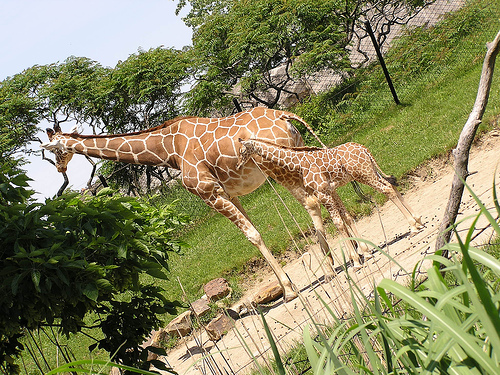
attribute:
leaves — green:
[55, 232, 163, 295]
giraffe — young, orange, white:
[236, 136, 425, 273]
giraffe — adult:
[42, 107, 373, 301]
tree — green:
[2, 127, 200, 370]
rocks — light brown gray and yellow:
[146, 271, 266, 345]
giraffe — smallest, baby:
[238, 139, 420, 259]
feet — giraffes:
[276, 273, 336, 289]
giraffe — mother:
[49, 107, 329, 282]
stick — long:
[435, 33, 496, 263]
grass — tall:
[319, 254, 496, 370]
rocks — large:
[177, 279, 277, 331]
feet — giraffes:
[274, 217, 416, 272]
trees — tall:
[3, 0, 350, 129]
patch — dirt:
[176, 154, 496, 328]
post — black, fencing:
[361, 20, 401, 101]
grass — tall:
[304, 258, 495, 349]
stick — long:
[438, 29, 495, 245]